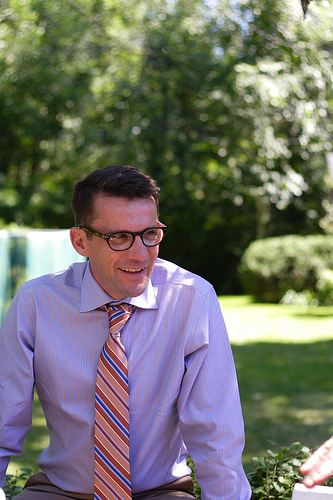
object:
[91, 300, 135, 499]
tie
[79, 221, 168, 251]
glasses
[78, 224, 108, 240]
frame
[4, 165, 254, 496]
man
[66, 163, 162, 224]
hair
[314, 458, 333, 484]
fingers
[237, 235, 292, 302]
bushes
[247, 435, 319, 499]
plant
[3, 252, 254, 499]
dress shirt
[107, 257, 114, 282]
wrinkles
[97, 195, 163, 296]
face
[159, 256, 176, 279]
reflection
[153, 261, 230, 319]
shoulder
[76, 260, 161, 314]
collar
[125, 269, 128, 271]
teeth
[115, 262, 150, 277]
mouth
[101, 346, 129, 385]
stripe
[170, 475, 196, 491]
pocket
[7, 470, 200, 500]
pants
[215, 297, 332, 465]
grass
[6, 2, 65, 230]
trees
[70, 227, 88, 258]
ear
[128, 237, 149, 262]
nose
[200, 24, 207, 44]
leaf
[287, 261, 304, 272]
leaves